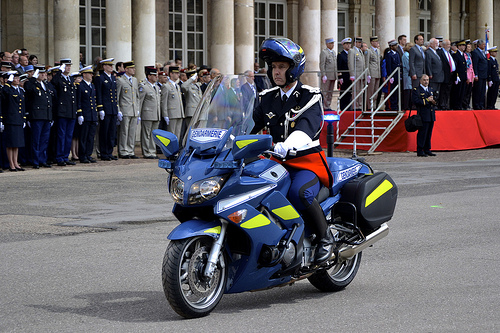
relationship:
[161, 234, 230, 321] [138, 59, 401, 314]
wheels on bike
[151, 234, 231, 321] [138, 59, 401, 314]
wheels on bike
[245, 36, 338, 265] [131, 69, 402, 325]
he on motorcycle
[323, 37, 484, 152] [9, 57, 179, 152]
people saluting crowd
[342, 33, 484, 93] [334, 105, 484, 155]
people standing stand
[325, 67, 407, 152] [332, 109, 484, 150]
stairs to stage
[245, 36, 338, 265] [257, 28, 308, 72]
he wearing helmet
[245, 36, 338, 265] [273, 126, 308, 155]
he wearing gloves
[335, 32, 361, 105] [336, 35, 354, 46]
man wearing hat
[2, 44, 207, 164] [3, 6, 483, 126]
people standing building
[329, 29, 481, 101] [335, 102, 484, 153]
people standing platform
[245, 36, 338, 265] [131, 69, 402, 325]
he riding motorcycle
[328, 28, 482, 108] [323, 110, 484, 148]
people on band stand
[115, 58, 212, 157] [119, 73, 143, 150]
men dressed suits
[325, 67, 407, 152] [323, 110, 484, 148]
stairs leading to the band stand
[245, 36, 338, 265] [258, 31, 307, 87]
he is wearing helmet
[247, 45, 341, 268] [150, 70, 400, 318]
he is on a motorcycle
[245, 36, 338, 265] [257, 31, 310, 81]
he is wearing a helmet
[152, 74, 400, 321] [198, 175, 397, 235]
bike has stripes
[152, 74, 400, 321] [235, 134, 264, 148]
bike has stripes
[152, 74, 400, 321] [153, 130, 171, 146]
bike has stripes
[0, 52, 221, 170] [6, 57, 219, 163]
crowd are all dressed in a uniform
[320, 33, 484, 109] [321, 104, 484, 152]
they are standing on a stage